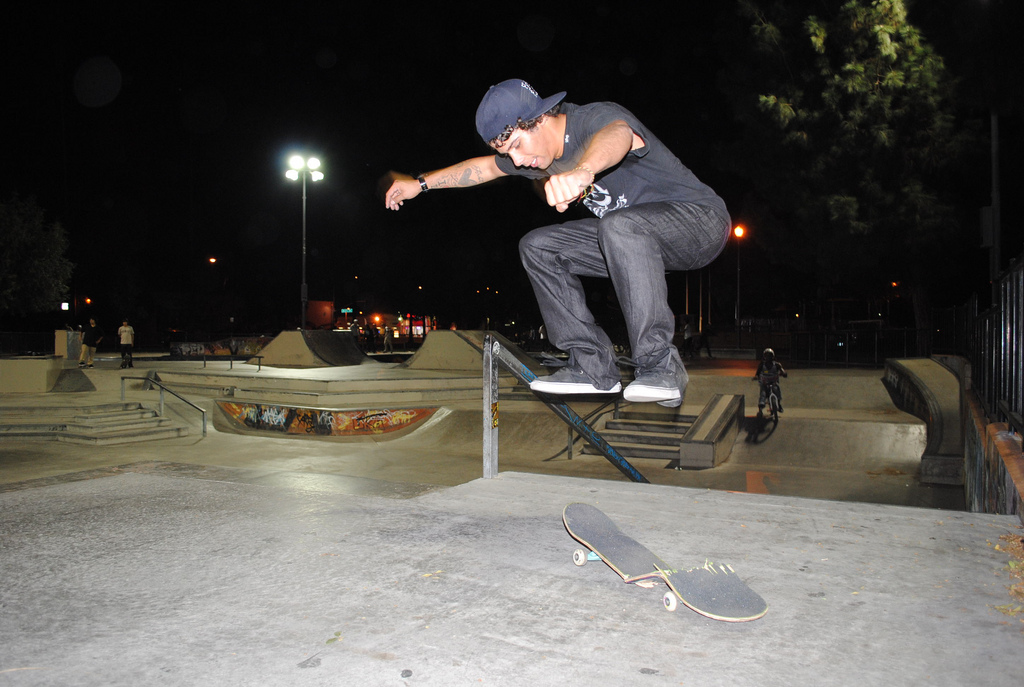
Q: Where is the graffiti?
A: On the walls.